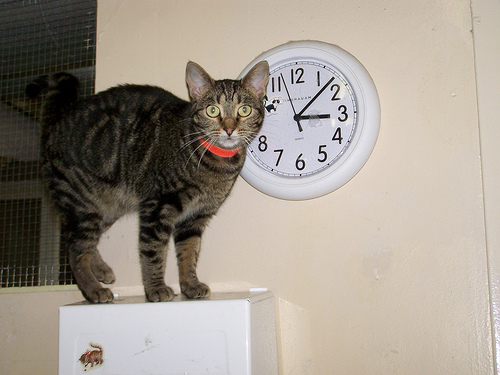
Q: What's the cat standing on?
A: A white solid board.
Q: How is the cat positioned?
A: It's lifting itself on all of it's four legs.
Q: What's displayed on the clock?
A: Numbers.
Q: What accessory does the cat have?
A: A red collar.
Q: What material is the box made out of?
A: Metal.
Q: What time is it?
A: 3:12.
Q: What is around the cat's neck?
A: Red collar.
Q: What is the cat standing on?
A: White box.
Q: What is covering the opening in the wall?
A: Metal mesh.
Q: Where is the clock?
A: On the wall.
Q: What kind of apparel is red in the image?
A: A cat collar.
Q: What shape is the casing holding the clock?
A: Circle.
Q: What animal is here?
A: Cat.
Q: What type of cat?
A: Tabby.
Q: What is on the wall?
A: Clock.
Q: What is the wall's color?
A: White.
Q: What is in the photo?
A: A cat.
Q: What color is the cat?
A: Brown.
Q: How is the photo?
A: Clear.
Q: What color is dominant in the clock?
A: White.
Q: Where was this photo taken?
A: In a kitchen.